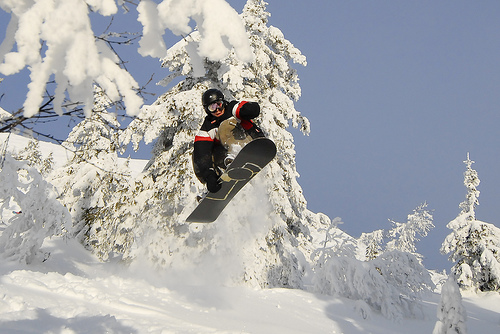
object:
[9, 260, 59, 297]
snow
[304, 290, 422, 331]
ground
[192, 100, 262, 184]
jacket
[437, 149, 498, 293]
tree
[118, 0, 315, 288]
tree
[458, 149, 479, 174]
cross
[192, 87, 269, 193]
man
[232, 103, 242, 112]
trim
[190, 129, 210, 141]
trim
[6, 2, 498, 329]
day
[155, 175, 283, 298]
snow falling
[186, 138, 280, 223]
board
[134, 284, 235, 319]
snow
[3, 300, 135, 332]
shadow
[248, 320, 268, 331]
snow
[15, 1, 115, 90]
trees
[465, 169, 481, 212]
top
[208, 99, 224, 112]
goggles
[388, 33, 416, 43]
air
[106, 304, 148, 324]
snow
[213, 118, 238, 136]
knee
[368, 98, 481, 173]
mid air